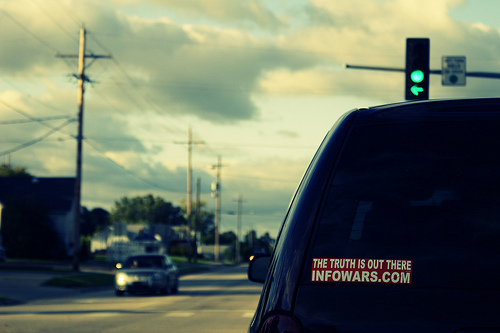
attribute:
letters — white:
[313, 259, 413, 284]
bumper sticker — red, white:
[310, 251, 418, 292]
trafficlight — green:
[406, 37, 429, 101]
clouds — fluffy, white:
[4, 4, 478, 125]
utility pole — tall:
[52, 24, 116, 271]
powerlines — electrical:
[10, 2, 245, 221]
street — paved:
[0, 256, 270, 332]